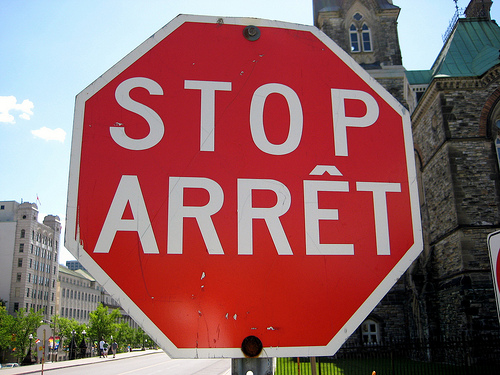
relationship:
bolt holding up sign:
[234, 334, 269, 359] [55, 14, 436, 374]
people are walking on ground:
[110, 339, 118, 358] [0, 350, 278, 375]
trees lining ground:
[6, 269, 190, 368] [0, 350, 278, 375]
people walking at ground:
[110, 339, 118, 358] [0, 350, 278, 375]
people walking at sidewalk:
[88, 330, 122, 362] [4, 334, 173, 372]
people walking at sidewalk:
[81, 337, 118, 360] [1, 345, 167, 374]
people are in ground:
[110, 339, 118, 358] [0, 350, 278, 375]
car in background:
[2, 360, 22, 368] [8, 332, 157, 367]